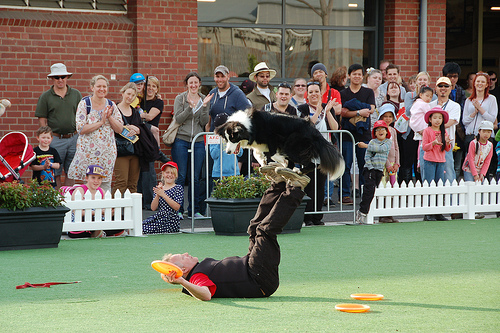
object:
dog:
[202, 102, 364, 195]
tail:
[316, 139, 344, 183]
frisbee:
[151, 260, 184, 278]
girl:
[462, 121, 494, 218]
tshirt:
[423, 126, 453, 163]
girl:
[423, 107, 449, 220]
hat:
[424, 107, 450, 124]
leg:
[255, 192, 296, 257]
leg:
[245, 185, 280, 249]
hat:
[249, 62, 278, 83]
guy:
[245, 60, 277, 107]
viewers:
[33, 59, 494, 224]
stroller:
[0, 131, 39, 187]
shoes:
[272, 166, 311, 190]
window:
[199, 2, 382, 78]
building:
[1, 2, 485, 192]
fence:
[367, 175, 500, 224]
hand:
[165, 271, 185, 284]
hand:
[201, 92, 215, 105]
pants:
[248, 183, 307, 263]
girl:
[140, 161, 186, 233]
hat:
[160, 162, 179, 171]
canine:
[183, 85, 373, 188]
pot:
[203, 197, 310, 236]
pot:
[0, 205, 71, 251]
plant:
[1, 179, 66, 211]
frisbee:
[335, 303, 371, 313]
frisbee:
[351, 293, 385, 300]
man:
[35, 62, 80, 188]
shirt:
[34, 84, 82, 136]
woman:
[67, 74, 125, 190]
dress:
[67, 97, 125, 183]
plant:
[210, 171, 274, 201]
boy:
[27, 125, 62, 188]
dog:
[214, 104, 344, 187]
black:
[271, 118, 319, 156]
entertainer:
[159, 164, 311, 301]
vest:
[182, 255, 265, 298]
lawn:
[348, 216, 499, 277]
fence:
[60, 187, 142, 236]